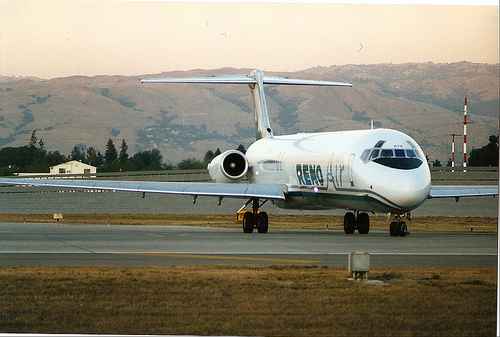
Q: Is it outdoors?
A: Yes, it is outdoors.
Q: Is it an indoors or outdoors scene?
A: It is outdoors.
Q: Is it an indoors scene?
A: No, it is outdoors.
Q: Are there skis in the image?
A: No, there are no skis.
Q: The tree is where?
A: The tree is in the field.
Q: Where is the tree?
A: The tree is in the field.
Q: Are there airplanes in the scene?
A: Yes, there is an airplane.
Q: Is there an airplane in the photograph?
A: Yes, there is an airplane.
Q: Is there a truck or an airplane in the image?
A: Yes, there is an airplane.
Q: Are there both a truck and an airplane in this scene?
A: No, there is an airplane but no trucks.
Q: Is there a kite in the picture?
A: No, there are no kites.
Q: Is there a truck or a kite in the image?
A: No, there are no kites or trucks.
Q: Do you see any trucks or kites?
A: No, there are no kites or trucks.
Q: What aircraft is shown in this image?
A: The aircraft is an airplane.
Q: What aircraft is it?
A: The aircraft is an airplane.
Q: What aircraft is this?
A: This is an airplane.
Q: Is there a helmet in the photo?
A: No, there are no helmets.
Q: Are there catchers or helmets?
A: No, there are no helmets or catchers.